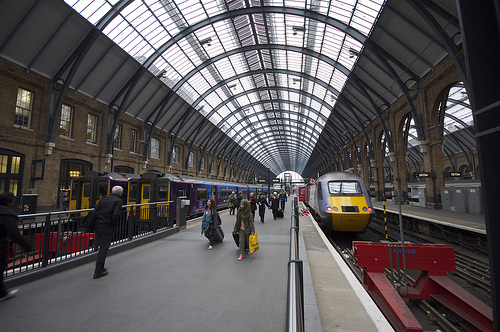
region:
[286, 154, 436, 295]
the train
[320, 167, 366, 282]
the train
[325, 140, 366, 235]
the train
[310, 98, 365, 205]
the train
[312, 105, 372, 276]
the train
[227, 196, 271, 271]
woman carrying yellow shopping bag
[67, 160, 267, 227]
two commuter trains on tracks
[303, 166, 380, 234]
silver and yellow train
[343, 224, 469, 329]
red stop barrier on track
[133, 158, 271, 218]
purple and blue commuter train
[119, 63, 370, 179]
glass domed ceiling in station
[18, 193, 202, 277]
fence between sidewalk and trains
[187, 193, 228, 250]
woman pulling a suitcase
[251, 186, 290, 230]
couple holding hands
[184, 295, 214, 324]
part of a floor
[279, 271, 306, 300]
part of a metal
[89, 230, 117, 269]
part of atrouser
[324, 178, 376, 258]
front of a train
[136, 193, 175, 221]
part of a fence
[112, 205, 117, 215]
part of an elbow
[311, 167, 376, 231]
Front of subway train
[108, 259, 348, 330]
Subway platform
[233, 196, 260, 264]
Lady carrying a yellow bag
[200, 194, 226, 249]
Woman pulling luggage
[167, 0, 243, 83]
Fluorescent subway lighting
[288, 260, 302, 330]
Metal protective railing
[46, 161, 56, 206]
Brown brick wall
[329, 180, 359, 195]
Front car subway train window reflecting Fluorescent lighting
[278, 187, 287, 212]
Person wearing a blue jacket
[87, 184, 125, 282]
Walking white haired gentleman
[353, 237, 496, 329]
A red train stop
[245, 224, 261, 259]
a yellow shopping bag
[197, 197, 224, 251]
a women pulls her luggage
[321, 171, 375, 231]
The yellow and grey front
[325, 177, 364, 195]
the trains windshield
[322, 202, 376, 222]
head lights on the train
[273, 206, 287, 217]
the bag being pulled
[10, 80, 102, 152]
a row of windows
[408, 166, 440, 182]
a sign on the wall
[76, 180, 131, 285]
a man with a bag